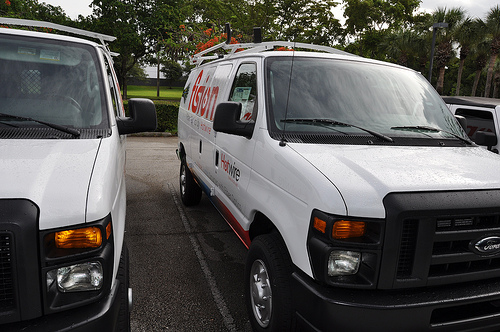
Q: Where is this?
A: This is at the parking lot.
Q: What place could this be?
A: It is a parking lot.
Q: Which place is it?
A: It is a parking lot.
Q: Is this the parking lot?
A: Yes, it is the parking lot.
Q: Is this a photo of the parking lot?
A: Yes, it is showing the parking lot.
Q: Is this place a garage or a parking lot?
A: It is a parking lot.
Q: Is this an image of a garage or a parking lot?
A: It is showing a parking lot.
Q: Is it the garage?
A: No, it is the parking lot.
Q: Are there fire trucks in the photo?
A: No, there are no fire trucks.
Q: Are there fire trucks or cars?
A: No, there are no fire trucks or cars.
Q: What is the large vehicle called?
A: The vehicle is a van.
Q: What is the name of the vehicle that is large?
A: The vehicle is a van.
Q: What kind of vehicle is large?
A: The vehicle is a van.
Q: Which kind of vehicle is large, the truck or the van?
A: The van is large.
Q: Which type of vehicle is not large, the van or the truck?
A: The truck is not large.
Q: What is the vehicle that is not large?
A: The vehicle is a truck.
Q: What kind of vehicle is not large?
A: The vehicle is a truck.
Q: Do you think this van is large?
A: Yes, the van is large.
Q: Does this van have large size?
A: Yes, the van is large.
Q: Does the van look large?
A: Yes, the van is large.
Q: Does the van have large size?
A: Yes, the van is large.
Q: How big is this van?
A: The van is large.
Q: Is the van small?
A: No, the van is large.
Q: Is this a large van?
A: Yes, this is a large van.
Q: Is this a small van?
A: No, this is a large van.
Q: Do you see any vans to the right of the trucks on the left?
A: Yes, there is a van to the right of the trucks.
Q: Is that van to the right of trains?
A: No, the van is to the right of the trucks.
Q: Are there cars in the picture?
A: No, there are no cars.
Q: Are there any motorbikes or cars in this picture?
A: No, there are no cars or motorbikes.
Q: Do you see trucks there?
A: Yes, there are trucks.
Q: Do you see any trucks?
A: Yes, there are trucks.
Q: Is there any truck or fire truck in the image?
A: Yes, there are trucks.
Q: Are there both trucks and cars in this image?
A: No, there are trucks but no cars.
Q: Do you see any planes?
A: No, there are no planes.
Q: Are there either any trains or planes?
A: No, there are no planes or trains.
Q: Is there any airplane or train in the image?
A: No, there are no airplanes or trains.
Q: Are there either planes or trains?
A: No, there are no planes or trains.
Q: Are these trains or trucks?
A: These are trucks.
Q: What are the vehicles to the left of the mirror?
A: The vehicles are trucks.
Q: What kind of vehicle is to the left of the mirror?
A: The vehicles are trucks.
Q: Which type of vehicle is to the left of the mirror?
A: The vehicles are trucks.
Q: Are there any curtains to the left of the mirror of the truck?
A: No, there are trucks to the left of the mirror.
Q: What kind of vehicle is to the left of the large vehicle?
A: The vehicles are trucks.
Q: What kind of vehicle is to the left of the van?
A: The vehicles are trucks.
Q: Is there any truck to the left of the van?
A: Yes, there are trucks to the left of the van.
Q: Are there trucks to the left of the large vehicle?
A: Yes, there are trucks to the left of the van.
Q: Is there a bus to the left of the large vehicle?
A: No, there are trucks to the left of the van.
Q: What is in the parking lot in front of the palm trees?
A: The trucks are in the parking lot.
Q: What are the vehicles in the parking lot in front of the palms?
A: The vehicles are trucks.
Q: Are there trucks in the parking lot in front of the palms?
A: Yes, there are trucks in the parking lot.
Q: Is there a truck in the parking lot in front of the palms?
A: Yes, there are trucks in the parking lot.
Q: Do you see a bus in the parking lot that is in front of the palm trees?
A: No, there are trucks in the parking lot.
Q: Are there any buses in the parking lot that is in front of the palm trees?
A: No, there are trucks in the parking lot.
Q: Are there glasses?
A: No, there are no glasses.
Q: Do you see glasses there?
A: No, there are no glasses.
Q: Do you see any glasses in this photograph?
A: No, there are no glasses.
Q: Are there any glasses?
A: No, there are no glasses.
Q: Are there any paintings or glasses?
A: No, there are no glasses or paintings.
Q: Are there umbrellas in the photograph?
A: No, there are no umbrellas.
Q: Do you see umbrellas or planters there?
A: No, there are no umbrellas or planters.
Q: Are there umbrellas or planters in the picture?
A: No, there are no umbrellas or planters.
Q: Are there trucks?
A: Yes, there is a truck.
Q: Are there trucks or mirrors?
A: Yes, there is a truck.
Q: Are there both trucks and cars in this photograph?
A: No, there is a truck but no cars.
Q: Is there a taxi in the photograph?
A: No, there are no taxis.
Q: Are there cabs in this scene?
A: No, there are no cabs.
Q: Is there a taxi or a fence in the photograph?
A: No, there are no taxis or fences.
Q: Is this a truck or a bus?
A: This is a truck.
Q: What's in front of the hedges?
A: The truck is in front of the hedges.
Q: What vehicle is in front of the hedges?
A: The vehicle is a truck.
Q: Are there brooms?
A: No, there are no brooms.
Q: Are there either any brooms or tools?
A: No, there are no brooms or tools.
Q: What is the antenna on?
A: The antenna is on the truck.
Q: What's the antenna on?
A: The antenna is on the truck.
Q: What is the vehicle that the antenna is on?
A: The vehicle is a truck.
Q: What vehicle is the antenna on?
A: The antenna is on the truck.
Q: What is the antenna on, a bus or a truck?
A: The antenna is on a truck.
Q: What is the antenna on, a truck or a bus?
A: The antenna is on a truck.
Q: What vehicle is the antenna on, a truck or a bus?
A: The antenna is on a truck.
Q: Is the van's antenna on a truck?
A: Yes, the antenna is on a truck.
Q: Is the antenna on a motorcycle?
A: No, the antenna is on a truck.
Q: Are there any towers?
A: No, there are no towers.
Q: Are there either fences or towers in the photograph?
A: No, there are no towers or fences.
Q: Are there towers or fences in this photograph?
A: No, there are no towers or fences.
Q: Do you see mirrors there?
A: Yes, there is a mirror.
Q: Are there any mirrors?
A: Yes, there is a mirror.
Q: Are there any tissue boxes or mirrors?
A: Yes, there is a mirror.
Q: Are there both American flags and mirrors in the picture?
A: No, there is a mirror but no American flags.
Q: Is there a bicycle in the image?
A: No, there are no bicycles.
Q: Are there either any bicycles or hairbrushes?
A: No, there are no bicycles or hairbrushes.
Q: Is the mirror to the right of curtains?
A: No, the mirror is to the right of the trucks.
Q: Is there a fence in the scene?
A: No, there are no fences.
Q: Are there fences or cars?
A: No, there are no fences or cars.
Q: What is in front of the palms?
A: The parking lot is in front of the palms.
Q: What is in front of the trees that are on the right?
A: The parking lot is in front of the palms.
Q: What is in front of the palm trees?
A: The parking lot is in front of the palms.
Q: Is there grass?
A: Yes, there is grass.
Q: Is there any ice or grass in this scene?
A: Yes, there is grass.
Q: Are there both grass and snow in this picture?
A: No, there is grass but no snow.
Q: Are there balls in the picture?
A: No, there are no balls.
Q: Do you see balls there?
A: No, there are no balls.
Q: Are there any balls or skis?
A: No, there are no balls or skis.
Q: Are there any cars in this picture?
A: No, there are no cars.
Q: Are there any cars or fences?
A: No, there are no cars or fences.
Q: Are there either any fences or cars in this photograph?
A: No, there are no cars or fences.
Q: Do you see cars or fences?
A: No, there are no cars or fences.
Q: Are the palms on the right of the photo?
A: Yes, the palms are on the right of the image.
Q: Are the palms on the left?
A: No, the palms are on the right of the image.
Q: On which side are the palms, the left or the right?
A: The palms are on the right of the image.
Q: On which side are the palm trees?
A: The palm trees are on the right of the image.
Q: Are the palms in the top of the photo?
A: Yes, the palms are in the top of the image.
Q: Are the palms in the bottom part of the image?
A: No, the palms are in the top of the image.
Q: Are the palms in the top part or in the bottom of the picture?
A: The palms are in the top of the image.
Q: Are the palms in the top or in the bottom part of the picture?
A: The palms are in the top of the image.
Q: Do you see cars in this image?
A: No, there are no cars.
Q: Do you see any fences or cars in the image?
A: No, there are no cars or fences.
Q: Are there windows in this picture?
A: Yes, there is a window.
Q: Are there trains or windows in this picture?
A: Yes, there is a window.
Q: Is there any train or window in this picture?
A: Yes, there is a window.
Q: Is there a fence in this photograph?
A: No, there are no fences.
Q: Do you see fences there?
A: No, there are no fences.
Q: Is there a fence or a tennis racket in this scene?
A: No, there are no fences or rackets.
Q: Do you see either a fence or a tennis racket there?
A: No, there are no fences or rackets.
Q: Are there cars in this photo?
A: No, there are no cars.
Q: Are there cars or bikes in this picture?
A: No, there are no cars or bikes.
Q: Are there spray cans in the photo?
A: No, there are no spray cans.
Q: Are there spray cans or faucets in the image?
A: No, there are no spray cans or faucets.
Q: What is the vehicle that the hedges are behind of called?
A: The vehicle is a truck.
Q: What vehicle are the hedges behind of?
A: The hedges are behind the truck.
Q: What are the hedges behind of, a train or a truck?
A: The hedges are behind a truck.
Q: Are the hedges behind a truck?
A: Yes, the hedges are behind a truck.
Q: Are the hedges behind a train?
A: No, the hedges are behind a truck.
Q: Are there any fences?
A: No, there are no fences.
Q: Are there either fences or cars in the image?
A: No, there are no fences or cars.